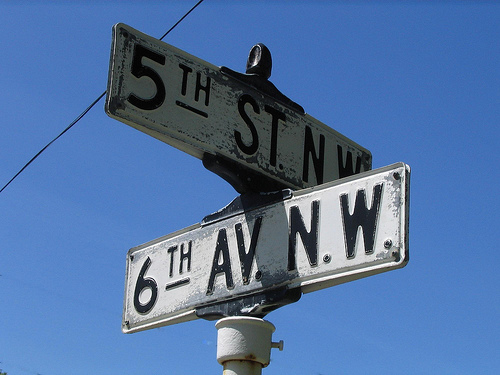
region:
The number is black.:
[132, 254, 162, 319]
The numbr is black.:
[122, 37, 172, 117]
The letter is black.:
[227, 85, 268, 160]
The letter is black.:
[260, 95, 291, 172]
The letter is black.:
[295, 118, 327, 184]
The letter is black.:
[202, 222, 233, 297]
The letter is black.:
[230, 215, 261, 285]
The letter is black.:
[277, 196, 323, 271]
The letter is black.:
[331, 178, 381, 263]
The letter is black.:
[176, 238, 195, 274]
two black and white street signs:
[97, 15, 406, 332]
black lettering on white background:
[206, 181, 382, 299]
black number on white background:
[122, 35, 169, 107]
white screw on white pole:
[271, 339, 285, 349]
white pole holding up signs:
[214, 315, 274, 372]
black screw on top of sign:
[234, 33, 273, 74]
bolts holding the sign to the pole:
[122, 167, 402, 332]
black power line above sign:
[1, 0, 214, 208]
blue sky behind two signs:
[6, 7, 496, 369]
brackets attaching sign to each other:
[203, 155, 275, 210]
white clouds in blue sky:
[362, 37, 406, 62]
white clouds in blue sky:
[410, 69, 461, 120]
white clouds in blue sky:
[401, 282, 461, 319]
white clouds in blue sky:
[298, 298, 365, 344]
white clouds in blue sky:
[39, 273, 92, 330]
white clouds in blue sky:
[42, 166, 104, 216]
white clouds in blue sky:
[57, 168, 165, 235]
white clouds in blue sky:
[23, 77, 65, 121]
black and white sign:
[110, 166, 401, 308]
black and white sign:
[101, 18, 288, 164]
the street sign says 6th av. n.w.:
[121, 153, 416, 325]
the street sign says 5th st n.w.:
[97, 28, 381, 208]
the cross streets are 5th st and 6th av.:
[107, 17, 398, 334]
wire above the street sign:
[1, 8, 199, 216]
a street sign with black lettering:
[98, 3, 416, 373]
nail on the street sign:
[274, 325, 294, 357]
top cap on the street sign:
[238, 23, 278, 80]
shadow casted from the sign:
[228, 157, 312, 305]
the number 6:
[127, 254, 164, 331]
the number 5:
[97, 20, 177, 137]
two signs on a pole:
[95, 15, 415, 371]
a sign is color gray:
[107, 158, 417, 338]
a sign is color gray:
[101, 17, 378, 191]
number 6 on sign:
[127, 243, 165, 322]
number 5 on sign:
[125, 36, 174, 111]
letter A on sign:
[199, 227, 234, 299]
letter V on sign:
[231, 213, 262, 285]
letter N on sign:
[281, 199, 323, 276]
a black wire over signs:
[2, 4, 227, 239]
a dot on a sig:
[379, 235, 396, 252]